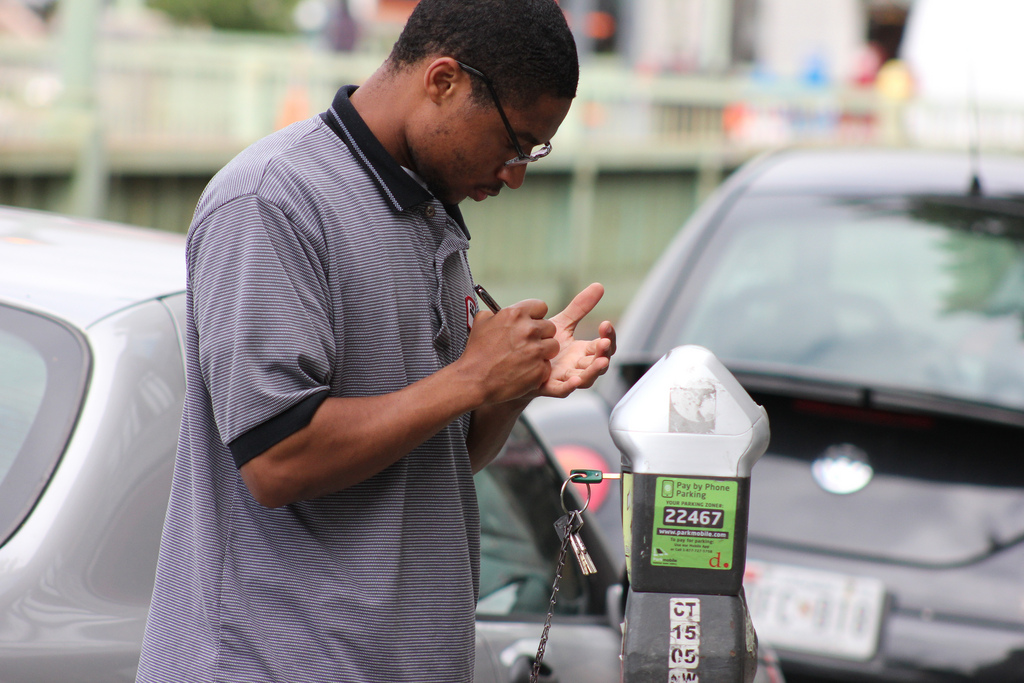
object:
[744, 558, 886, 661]
plate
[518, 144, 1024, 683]
car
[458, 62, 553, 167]
glasses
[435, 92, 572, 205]
face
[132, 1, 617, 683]
man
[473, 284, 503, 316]
blackpen